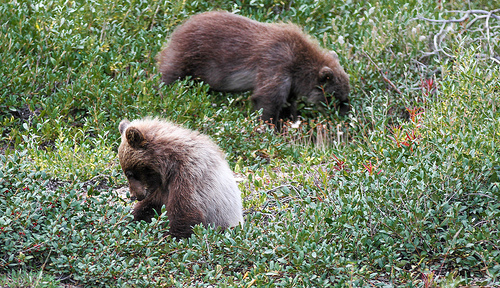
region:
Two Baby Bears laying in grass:
[96, 3, 407, 249]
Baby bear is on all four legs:
[146, 0, 377, 138]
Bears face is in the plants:
[155, 10, 375, 141]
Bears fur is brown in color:
[91, 11, 356, 253]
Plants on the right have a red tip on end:
[315, 75, 465, 205]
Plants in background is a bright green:
[0, 5, 175, 125]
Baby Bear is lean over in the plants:
[100, 110, 255, 246]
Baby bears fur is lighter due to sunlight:
[127, 106, 247, 236]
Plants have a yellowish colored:
[33, 117, 334, 198]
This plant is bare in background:
[418, 2, 498, 59]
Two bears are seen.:
[112, 21, 359, 227]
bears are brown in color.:
[110, 20, 332, 210]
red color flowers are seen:
[313, 88, 435, 183]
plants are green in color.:
[292, 176, 397, 250]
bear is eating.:
[300, 68, 422, 166]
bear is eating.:
[273, 46, 410, 145]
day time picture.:
[23, 31, 468, 251]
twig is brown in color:
[425, 11, 499, 53]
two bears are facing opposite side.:
[117, 18, 371, 255]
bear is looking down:
[113, 114, 188, 212]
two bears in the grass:
[133, 14, 349, 242]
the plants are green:
[0, 2, 497, 286]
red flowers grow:
[328, 70, 438, 190]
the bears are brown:
[126, 20, 351, 225]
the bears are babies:
[121, 11, 353, 237]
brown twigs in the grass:
[417, 1, 499, 71]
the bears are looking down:
[125, 9, 352, 234]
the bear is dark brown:
[161, 10, 349, 117]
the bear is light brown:
[115, 119, 242, 231]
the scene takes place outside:
[0, 0, 495, 285]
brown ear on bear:
[124, 125, 146, 147]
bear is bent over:
[115, 115, 246, 242]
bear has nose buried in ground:
[157, 8, 353, 133]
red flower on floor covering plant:
[362, 159, 377, 177]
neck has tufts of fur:
[130, 114, 183, 138]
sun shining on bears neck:
[124, 112, 196, 147]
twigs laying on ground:
[420, 6, 498, 67]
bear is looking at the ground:
[118, 116, 247, 243]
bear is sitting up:
[116, 116, 245, 243]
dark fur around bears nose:
[122, 165, 162, 191]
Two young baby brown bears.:
[116, 11, 351, 228]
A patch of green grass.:
[2, 48, 89, 98]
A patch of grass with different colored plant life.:
[0, 238, 497, 286]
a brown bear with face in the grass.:
[161, 10, 353, 125]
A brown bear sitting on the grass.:
[108, 120, 245, 242]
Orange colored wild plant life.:
[379, 109, 431, 152]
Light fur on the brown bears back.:
[200, 161, 238, 208]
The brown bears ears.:
[119, 119, 144, 146]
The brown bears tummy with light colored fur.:
[197, 69, 256, 89]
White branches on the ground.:
[400, 10, 499, 64]